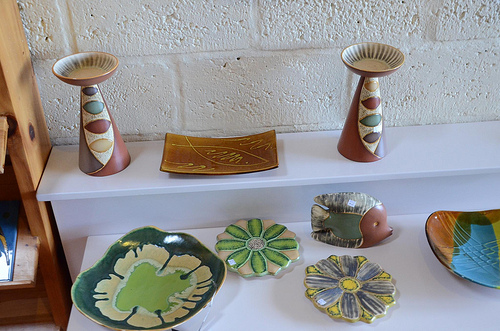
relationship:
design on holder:
[361, 112, 383, 123] [333, 42, 405, 162]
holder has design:
[328, 42, 405, 161] [80, 85, 111, 166]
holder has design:
[45, 47, 132, 179] [362, 76, 384, 149]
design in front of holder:
[80, 85, 111, 166] [328, 42, 405, 161]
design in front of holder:
[362, 76, 384, 149] [45, 47, 132, 179]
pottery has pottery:
[215, 224, 290, 271] [211, 217, 301, 279]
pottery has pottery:
[302, 251, 398, 326] [302, 251, 398, 326]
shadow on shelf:
[189, 262, 246, 328] [36, 119, 498, 329]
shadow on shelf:
[264, 258, 344, 328] [36, 119, 498, 329]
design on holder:
[80, 97, 108, 114] [50, 47, 132, 179]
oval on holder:
[84, 137, 113, 154] [50, 47, 132, 179]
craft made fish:
[309, 194, 392, 247] [307, 192, 395, 245]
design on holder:
[354, 85, 386, 148] [333, 42, 405, 162]